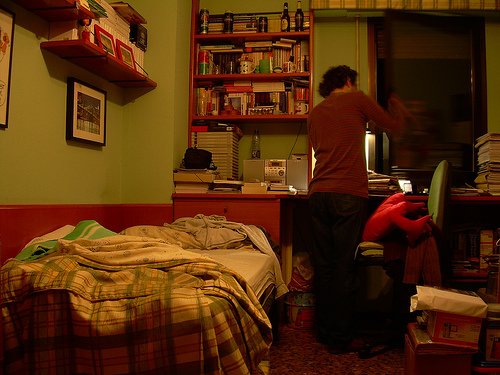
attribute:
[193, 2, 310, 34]
beet bottles — empty, beer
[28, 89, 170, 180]
wall — green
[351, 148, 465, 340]
chair — green 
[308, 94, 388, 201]
shirt — red, striped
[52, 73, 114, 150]
artwork — framed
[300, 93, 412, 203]
shirt — striped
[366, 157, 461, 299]
chair — green, swivel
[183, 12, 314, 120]
shelf — cluttered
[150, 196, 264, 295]
pants — grey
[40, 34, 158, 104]
shelf — wood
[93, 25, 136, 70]
frames — red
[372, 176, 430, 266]
pillow — red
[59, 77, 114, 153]
picture — black, framed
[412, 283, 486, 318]
paper — copier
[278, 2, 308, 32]
bottles — beer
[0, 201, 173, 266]
paneling — red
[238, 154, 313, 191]
stereo — silver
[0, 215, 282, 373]
bed — unmade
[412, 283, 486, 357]
boxes — cardboard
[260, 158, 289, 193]
stereo — silver 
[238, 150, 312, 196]
speakers — silver 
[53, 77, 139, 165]
frame — black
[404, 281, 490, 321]
paper — copier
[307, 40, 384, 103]
hair — brown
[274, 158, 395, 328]
pants — black